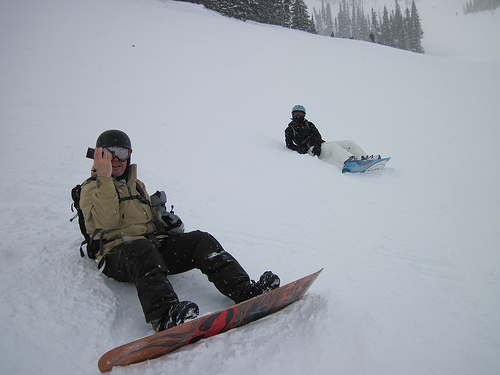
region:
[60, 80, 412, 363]
the men are sitting in the snow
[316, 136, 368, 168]
the man is wearing white pants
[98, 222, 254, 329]
the man is wearing black pants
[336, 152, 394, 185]
the man has a blue board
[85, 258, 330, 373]
the man has a red board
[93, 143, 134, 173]
the man is wearing big goggles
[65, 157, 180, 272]
the man is wearing a brown jacket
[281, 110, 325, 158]
the man is wearing a black jacket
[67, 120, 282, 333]
the man is taking a selfie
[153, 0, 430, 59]
the trees are far away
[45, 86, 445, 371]
Two men enjoying snowboard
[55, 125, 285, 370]
Man using electronic device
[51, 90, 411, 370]
Friends snowboarding together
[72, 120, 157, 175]
Man wearing a helmet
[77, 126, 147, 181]
Man wearing his goggles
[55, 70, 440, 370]
Two men enjoying the snow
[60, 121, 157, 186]
Man taking a picture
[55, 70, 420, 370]
Snowboarders taking a rest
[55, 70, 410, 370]
Men on a snow covered hill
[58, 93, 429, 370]
Two men having fun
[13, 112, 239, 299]
male snow boarder sitting in white snow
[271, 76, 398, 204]
male snow boarder sitting in white snow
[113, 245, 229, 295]
male snow boarder wearing black pants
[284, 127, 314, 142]
male snow boarder wearing black jacket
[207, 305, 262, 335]
red and black snow board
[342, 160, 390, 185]
blue and white snow board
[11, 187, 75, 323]
white snow on mountain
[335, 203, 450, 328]
white snow on mountain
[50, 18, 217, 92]
white snow on mountain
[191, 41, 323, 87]
white snow on mountain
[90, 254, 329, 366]
a red snowboard on the ground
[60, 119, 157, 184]
a man wearing a helmet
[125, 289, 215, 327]
a black ski boot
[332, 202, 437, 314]
white snow on the ground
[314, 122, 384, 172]
white ski pants on a woman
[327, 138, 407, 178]
a blue snow board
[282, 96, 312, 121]
blue ski helmet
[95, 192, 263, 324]
black ski pants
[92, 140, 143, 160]
a man wearing ski goggles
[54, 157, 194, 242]
a man wearing a tan coat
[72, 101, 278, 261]
snowboarder taking a rest on slope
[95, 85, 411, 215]
two snowboarders resting on a slope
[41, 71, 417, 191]
snowboarders waiting to finish their journey down hill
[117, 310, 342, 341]
red snowboard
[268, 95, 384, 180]
snowboarder in white pants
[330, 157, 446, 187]
baby blue snowboard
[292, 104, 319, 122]
snowboarder wearing blue helmet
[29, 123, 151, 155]
black helmet and goggles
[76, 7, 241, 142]
big snowy slope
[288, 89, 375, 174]
snowboard posing for camera